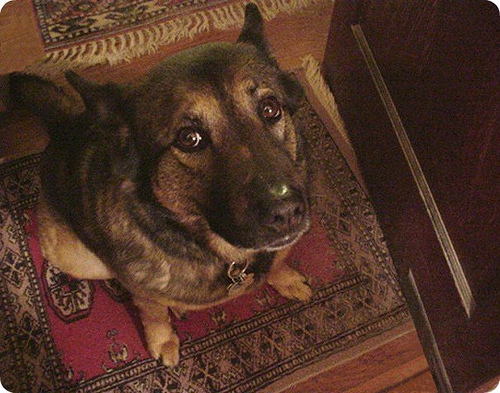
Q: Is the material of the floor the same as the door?
A: Yes, both the floor and the door are made of wood.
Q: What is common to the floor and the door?
A: The material, both the floor and the door are wooden.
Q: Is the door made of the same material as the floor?
A: Yes, both the door and the floor are made of wood.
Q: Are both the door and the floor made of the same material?
A: Yes, both the door and the floor are made of wood.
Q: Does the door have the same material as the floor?
A: Yes, both the door and the floor are made of wood.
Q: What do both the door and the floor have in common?
A: The material, both the door and the floor are wooden.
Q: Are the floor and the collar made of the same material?
A: No, the floor is made of wood and the collar is made of metal.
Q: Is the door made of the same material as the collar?
A: No, the door is made of wood and the collar is made of metal.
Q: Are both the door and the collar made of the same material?
A: No, the door is made of wood and the collar is made of metal.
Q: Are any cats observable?
A: No, there are no cats.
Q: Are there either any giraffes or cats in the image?
A: No, there are no cats or giraffes.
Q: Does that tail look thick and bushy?
A: Yes, the tail is thick and bushy.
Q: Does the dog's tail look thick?
A: Yes, the tail is thick.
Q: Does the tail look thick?
A: Yes, the tail is thick.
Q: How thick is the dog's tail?
A: The tail is thick.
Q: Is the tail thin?
A: No, the tail is thick.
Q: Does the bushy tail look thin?
A: No, the tail is thick.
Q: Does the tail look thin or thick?
A: The tail is thick.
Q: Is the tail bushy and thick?
A: Yes, the tail is bushy and thick.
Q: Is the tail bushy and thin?
A: No, the tail is bushy but thick.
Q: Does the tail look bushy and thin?
A: No, the tail is bushy but thick.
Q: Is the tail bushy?
A: Yes, the tail is bushy.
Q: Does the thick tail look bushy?
A: Yes, the tail is bushy.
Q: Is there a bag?
A: No, there are no bags.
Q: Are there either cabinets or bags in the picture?
A: No, there are no bags or cabinets.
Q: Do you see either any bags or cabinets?
A: No, there are no bags or cabinets.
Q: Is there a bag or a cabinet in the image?
A: No, there are no bags or cabinets.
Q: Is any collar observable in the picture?
A: Yes, there is a collar.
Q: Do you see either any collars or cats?
A: Yes, there is a collar.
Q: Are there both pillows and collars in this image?
A: No, there is a collar but no pillows.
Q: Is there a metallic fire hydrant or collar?
A: Yes, there is a metal collar.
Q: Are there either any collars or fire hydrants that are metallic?
A: Yes, the collar is metallic.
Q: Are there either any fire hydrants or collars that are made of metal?
A: Yes, the collar is made of metal.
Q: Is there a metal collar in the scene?
A: Yes, there is a metal collar.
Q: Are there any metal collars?
A: Yes, there is a metal collar.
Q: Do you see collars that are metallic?
A: Yes, there is a metal collar.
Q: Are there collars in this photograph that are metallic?
A: Yes, there is a collar that is metallic.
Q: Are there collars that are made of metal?
A: Yes, there is a collar that is made of metal.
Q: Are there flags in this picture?
A: No, there are no flags.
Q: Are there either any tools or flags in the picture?
A: No, there are no flags or tools.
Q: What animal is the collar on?
A: The collar is on the dog.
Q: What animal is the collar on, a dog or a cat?
A: The collar is on a dog.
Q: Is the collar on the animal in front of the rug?
A: Yes, the collar is on the dog.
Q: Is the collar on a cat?
A: No, the collar is on the dog.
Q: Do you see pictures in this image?
A: No, there are no pictures.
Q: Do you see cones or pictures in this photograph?
A: No, there are no pictures or cones.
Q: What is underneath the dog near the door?
A: The rug is underneath the dog.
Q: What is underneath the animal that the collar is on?
A: The rug is underneath the dog.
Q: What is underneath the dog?
A: The rug is underneath the dog.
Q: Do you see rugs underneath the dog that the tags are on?
A: Yes, there is a rug underneath the dog.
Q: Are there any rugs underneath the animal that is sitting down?
A: Yes, there is a rug underneath the dog.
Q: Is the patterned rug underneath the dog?
A: Yes, the rug is underneath the dog.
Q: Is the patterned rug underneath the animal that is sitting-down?
A: Yes, the rug is underneath the dog.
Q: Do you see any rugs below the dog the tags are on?
A: Yes, there is a rug below the dog.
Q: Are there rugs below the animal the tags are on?
A: Yes, there is a rug below the dog.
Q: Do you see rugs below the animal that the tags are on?
A: Yes, there is a rug below the dog.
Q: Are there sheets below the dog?
A: No, there is a rug below the dog.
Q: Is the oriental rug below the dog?
A: Yes, the rug is below the dog.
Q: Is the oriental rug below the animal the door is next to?
A: Yes, the rug is below the dog.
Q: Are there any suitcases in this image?
A: No, there are no suitcases.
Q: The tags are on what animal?
A: The tags are on the dog.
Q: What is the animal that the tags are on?
A: The animal is a dog.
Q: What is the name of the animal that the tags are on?
A: The animal is a dog.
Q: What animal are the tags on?
A: The tags are on the dog.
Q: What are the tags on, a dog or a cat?
A: The tags are on a dog.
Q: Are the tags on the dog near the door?
A: Yes, the tags are on the dog.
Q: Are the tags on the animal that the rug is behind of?
A: Yes, the tags are on the dog.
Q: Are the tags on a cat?
A: No, the tags are on the dog.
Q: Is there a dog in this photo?
A: Yes, there is a dog.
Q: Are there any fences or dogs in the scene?
A: Yes, there is a dog.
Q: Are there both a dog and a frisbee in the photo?
A: No, there is a dog but no frisbees.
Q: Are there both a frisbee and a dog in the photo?
A: No, there is a dog but no frisbees.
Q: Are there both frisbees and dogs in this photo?
A: No, there is a dog but no frisbees.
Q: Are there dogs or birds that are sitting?
A: Yes, the dog is sitting.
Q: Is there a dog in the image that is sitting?
A: Yes, there is a dog that is sitting.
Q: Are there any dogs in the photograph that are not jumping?
A: Yes, there is a dog that is sitting.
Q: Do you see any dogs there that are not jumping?
A: Yes, there is a dog that is sitting .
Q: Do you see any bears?
A: No, there are no bears.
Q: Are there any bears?
A: No, there are no bears.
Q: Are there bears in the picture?
A: No, there are no bears.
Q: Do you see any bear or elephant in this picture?
A: No, there are no bears or elephants.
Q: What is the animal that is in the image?
A: The animal is a dog.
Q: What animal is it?
A: The animal is a dog.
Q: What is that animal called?
A: This is a dog.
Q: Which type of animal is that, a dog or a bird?
A: This is a dog.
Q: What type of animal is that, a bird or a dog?
A: This is a dog.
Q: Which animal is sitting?
A: The animal is a dog.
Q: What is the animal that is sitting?
A: The animal is a dog.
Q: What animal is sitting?
A: The animal is a dog.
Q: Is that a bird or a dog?
A: That is a dog.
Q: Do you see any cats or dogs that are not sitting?
A: No, there is a dog but it is sitting.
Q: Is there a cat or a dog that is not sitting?
A: No, there is a dog but it is sitting.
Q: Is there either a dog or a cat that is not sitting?
A: No, there is a dog but it is sitting.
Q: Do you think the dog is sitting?
A: Yes, the dog is sitting.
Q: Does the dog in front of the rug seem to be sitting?
A: Yes, the dog is sitting.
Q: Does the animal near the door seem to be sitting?
A: Yes, the dog is sitting.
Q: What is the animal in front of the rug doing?
A: The dog is sitting.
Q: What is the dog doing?
A: The dog is sitting.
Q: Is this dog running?
A: No, the dog is sitting.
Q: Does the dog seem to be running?
A: No, the dog is sitting.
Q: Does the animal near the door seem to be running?
A: No, the dog is sitting.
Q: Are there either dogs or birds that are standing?
A: No, there is a dog but it is sitting.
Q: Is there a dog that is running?
A: No, there is a dog but it is sitting.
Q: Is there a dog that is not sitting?
A: No, there is a dog but it is sitting.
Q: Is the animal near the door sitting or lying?
A: The dog is sitting.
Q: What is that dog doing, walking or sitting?
A: The dog is sitting.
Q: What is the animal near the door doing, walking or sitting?
A: The dog is sitting.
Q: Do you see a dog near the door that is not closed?
A: Yes, there is a dog near the door.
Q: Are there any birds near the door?
A: No, there is a dog near the door.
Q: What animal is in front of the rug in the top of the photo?
A: The dog is in front of the rug.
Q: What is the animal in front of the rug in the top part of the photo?
A: The animal is a dog.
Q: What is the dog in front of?
A: The dog is in front of the rug.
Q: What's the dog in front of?
A: The dog is in front of the rug.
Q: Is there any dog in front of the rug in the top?
A: Yes, there is a dog in front of the rug.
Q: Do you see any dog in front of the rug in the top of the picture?
A: Yes, there is a dog in front of the rug.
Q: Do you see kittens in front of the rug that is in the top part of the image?
A: No, there is a dog in front of the rug.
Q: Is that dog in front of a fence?
A: No, the dog is in front of the rug.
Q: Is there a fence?
A: No, there are no fences.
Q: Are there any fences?
A: No, there are no fences.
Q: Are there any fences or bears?
A: No, there are no fences or bears.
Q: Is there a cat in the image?
A: No, there are no cats.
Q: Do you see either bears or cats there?
A: No, there are no cats or bears.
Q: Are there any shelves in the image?
A: No, there are no shelves.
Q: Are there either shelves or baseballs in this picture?
A: No, there are no shelves or baseballs.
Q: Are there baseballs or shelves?
A: No, there are no shelves or baseballs.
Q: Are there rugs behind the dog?
A: Yes, there is a rug behind the dog.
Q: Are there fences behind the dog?
A: No, there is a rug behind the dog.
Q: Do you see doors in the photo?
A: Yes, there is a door.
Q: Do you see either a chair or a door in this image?
A: Yes, there is a door.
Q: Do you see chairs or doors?
A: Yes, there is a door.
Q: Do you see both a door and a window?
A: No, there is a door but no windows.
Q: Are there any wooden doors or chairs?
A: Yes, there is a wood door.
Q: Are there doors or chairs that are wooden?
A: Yes, the door is wooden.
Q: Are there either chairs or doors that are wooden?
A: Yes, the door is wooden.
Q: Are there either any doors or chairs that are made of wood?
A: Yes, the door is made of wood.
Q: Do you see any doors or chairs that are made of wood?
A: Yes, the door is made of wood.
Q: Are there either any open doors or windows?
A: Yes, there is an open door.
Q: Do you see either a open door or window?
A: Yes, there is an open door.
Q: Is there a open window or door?
A: Yes, there is an open door.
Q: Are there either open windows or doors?
A: Yes, there is an open door.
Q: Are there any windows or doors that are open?
A: Yes, the door is open.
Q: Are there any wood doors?
A: Yes, there is a door that is made of wood.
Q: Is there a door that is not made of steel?
A: Yes, there is a door that is made of wood.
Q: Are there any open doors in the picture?
A: Yes, there is an open door.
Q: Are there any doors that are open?
A: Yes, there is a door that is open.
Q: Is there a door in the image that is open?
A: Yes, there is a door that is open.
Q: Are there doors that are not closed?
A: Yes, there is a open door.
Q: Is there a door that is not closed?
A: Yes, there is a open door.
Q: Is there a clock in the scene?
A: No, there are no clocks.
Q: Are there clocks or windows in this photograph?
A: No, there are no clocks or windows.